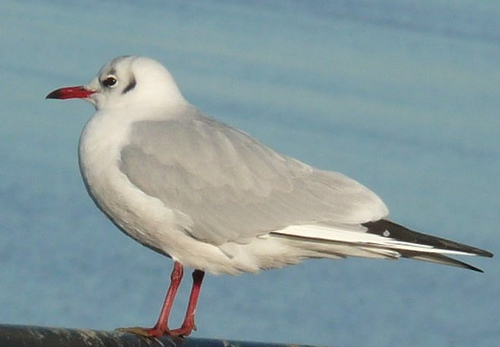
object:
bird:
[41, 53, 494, 340]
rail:
[0, 318, 316, 346]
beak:
[44, 83, 88, 101]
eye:
[99, 73, 120, 90]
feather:
[299, 222, 407, 240]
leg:
[153, 263, 183, 328]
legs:
[183, 269, 205, 326]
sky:
[0, 0, 499, 347]